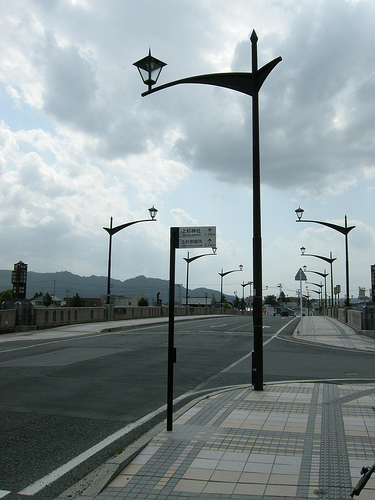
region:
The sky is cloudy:
[0, 7, 374, 241]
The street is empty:
[15, 301, 360, 466]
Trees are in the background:
[7, 257, 171, 298]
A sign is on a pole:
[160, 218, 225, 436]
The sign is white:
[164, 215, 225, 255]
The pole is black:
[159, 221, 187, 435]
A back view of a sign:
[289, 262, 311, 339]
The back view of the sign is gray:
[293, 266, 313, 341]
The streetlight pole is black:
[94, 203, 161, 308]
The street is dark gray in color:
[14, 346, 137, 424]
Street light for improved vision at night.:
[86, 201, 162, 317]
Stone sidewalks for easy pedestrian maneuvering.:
[202, 392, 366, 494]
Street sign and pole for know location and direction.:
[166, 223, 222, 438]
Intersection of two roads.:
[7, 314, 235, 414]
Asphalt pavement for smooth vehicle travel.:
[275, 337, 355, 382]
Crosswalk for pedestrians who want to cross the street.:
[128, 321, 281, 347]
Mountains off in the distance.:
[42, 262, 236, 313]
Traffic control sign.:
[292, 265, 310, 322]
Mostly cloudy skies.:
[28, 79, 219, 212]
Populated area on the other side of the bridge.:
[274, 294, 373, 317]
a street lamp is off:
[133, 47, 168, 87]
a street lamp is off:
[147, 204, 161, 217]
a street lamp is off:
[238, 261, 245, 271]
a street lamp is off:
[210, 242, 218, 253]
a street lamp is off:
[292, 203, 306, 217]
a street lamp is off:
[301, 261, 307, 270]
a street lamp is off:
[263, 283, 270, 292]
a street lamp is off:
[303, 274, 311, 284]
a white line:
[51, 415, 145, 485]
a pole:
[248, 201, 264, 385]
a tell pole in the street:
[165, 242, 184, 438]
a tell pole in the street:
[248, 95, 267, 402]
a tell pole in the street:
[105, 231, 111, 303]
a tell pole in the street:
[341, 234, 352, 300]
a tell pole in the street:
[328, 260, 336, 302]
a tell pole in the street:
[322, 275, 331, 303]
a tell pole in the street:
[184, 260, 192, 299]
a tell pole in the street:
[218, 272, 225, 299]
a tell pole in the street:
[240, 283, 246, 301]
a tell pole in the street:
[246, 283, 253, 298]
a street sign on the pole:
[167, 224, 217, 434]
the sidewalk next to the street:
[82, 376, 371, 497]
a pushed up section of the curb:
[96, 446, 138, 487]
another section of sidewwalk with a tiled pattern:
[291, 314, 374, 357]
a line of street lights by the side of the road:
[291, 205, 348, 325]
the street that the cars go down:
[4, 316, 374, 498]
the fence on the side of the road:
[6, 301, 235, 324]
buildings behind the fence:
[38, 286, 149, 307]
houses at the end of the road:
[259, 296, 305, 317]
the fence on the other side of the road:
[322, 306, 367, 339]